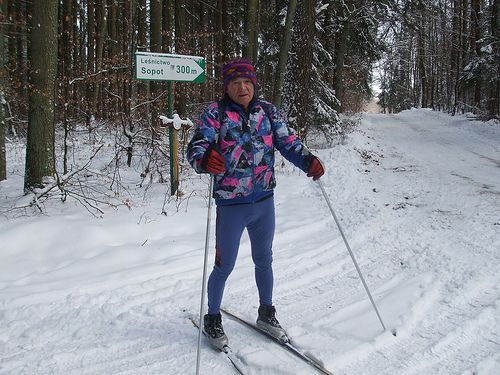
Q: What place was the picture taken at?
A: It was taken at the forest.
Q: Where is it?
A: This is at the forest.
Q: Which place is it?
A: It is a forest.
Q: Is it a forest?
A: Yes, it is a forest.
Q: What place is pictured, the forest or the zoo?
A: It is the forest.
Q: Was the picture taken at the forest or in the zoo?
A: It was taken at the forest.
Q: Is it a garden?
A: No, it is a forest.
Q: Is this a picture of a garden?
A: No, the picture is showing a forest.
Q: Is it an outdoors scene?
A: Yes, it is outdoors.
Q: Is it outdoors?
A: Yes, it is outdoors.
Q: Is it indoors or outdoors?
A: It is outdoors.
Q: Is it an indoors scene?
A: No, it is outdoors.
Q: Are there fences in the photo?
A: No, there are no fences.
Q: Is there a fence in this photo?
A: No, there are no fences.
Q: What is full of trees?
A: The forest is full of trees.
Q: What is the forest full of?
A: The forest is full of trees.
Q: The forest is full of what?
A: The forest is full of trees.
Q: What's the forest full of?
A: The forest is full of trees.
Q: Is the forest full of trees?
A: Yes, the forest is full of trees.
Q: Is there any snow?
A: Yes, there is snow.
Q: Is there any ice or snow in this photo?
A: Yes, there is snow.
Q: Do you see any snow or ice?
A: Yes, there is snow.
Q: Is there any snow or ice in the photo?
A: Yes, there is snow.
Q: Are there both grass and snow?
A: No, there is snow but no grass.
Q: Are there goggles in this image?
A: No, there are no goggles.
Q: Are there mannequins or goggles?
A: No, there are no goggles or mannequins.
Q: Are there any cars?
A: No, there are no cars.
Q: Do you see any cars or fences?
A: No, there are no cars or fences.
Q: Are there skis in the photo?
A: Yes, there are skis.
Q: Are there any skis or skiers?
A: Yes, there are skis.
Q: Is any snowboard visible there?
A: No, there are no snowboards.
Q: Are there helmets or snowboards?
A: No, there are no snowboards or helmets.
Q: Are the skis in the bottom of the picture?
A: Yes, the skis are in the bottom of the image.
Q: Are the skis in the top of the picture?
A: No, the skis are in the bottom of the image.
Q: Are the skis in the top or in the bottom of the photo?
A: The skis are in the bottom of the image.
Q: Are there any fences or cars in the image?
A: No, there are no cars or fences.